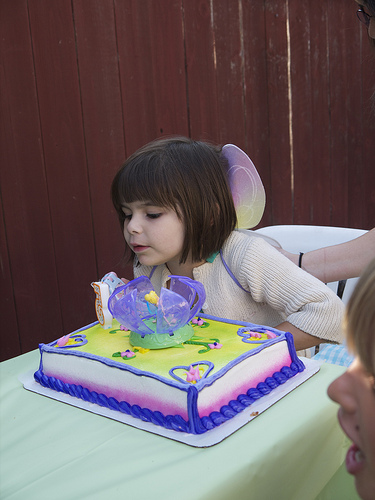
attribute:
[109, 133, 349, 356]
child — little, celebrating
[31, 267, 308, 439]
cake — birthday, white, colorful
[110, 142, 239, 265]
hair — black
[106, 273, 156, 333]
wing — nylon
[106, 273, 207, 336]
topper — purple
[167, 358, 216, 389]
heart — purple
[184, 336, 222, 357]
stem — green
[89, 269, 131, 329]
candle — 5th, number 5, orange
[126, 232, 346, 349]
sweater — white, cream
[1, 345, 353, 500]
table cloth — green, light green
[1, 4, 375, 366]
wall — wood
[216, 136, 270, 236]
wing — purple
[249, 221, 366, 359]
chair — white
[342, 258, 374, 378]
hair — blond